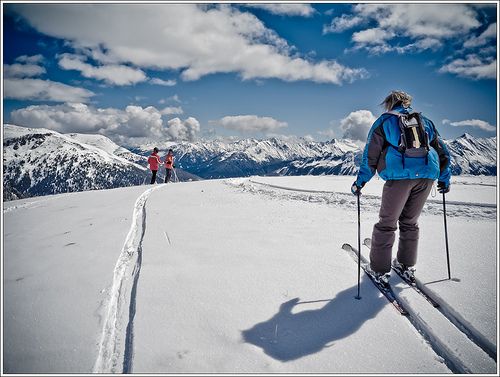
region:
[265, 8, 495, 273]
a person on skies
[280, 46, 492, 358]
a person on the snow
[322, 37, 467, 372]
a person skiing on the snow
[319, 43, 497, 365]
a person skiing on white snow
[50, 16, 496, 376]
a person skiing on a mountain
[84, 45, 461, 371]
person on a snow covered mountain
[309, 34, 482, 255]
a person wearing a jacket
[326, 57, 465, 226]
a person wearing a blue jacket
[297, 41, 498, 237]
a person wearing a black pack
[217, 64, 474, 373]
a shadow of a skier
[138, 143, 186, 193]
Two people on skiis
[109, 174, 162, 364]
ski tracks in the snow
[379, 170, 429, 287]
man wearing gray pants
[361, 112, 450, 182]
person wearing blue jackets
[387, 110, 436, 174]
person with gray backpack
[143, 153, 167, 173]
person wearing pink jacket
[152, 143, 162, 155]
person wearing a black hat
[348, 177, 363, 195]
Person wearing gloves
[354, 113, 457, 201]
Person holding ski poles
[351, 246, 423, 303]
person with snow boots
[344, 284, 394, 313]
edge of ski pole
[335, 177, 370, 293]
ski pole in skier's hand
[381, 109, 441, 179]
gray and black back pack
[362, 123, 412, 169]
black color on blue ski jacket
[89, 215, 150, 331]
long tracks in the sand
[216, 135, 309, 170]
snow covered mountain range above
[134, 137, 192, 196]
skiers in red and white jacket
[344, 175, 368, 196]
blue and white glove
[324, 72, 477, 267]
skier going down the mountain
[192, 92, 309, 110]
small area of blue skies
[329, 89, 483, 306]
woman skiing on the snow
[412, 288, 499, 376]
two thin tracks from the skis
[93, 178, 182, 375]
tracks in the snow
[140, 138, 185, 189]
two people standing on the snow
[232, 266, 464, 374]
shadow from the skier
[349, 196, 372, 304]
ski pole sticking in the ground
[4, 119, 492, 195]
mountain range covered in snow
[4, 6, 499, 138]
puffy white couds in the sky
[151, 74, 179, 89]
small thin cloud in the blue sky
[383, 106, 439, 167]
gray and black backpack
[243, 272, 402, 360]
A skier's dark shadow in the snow.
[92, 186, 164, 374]
Tracks made by a pair of skis.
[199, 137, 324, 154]
Group of snow capped mountains.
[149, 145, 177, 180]
Two skiers on top of a hill.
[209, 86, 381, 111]
The blue part of a clear sky.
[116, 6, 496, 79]
White clouds dancing in the sky.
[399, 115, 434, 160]
A black and white backpack.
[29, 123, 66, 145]
The pointed top of a mountain.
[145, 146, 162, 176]
Woman wearing a red coat.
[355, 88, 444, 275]
Woman wearing gray pants and blue jacket.